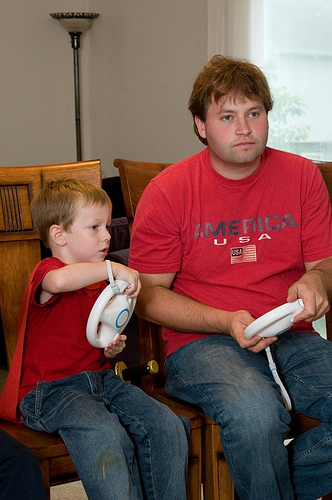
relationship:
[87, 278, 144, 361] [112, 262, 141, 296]
steering wheel in hands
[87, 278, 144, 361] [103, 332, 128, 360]
steering wheel in hands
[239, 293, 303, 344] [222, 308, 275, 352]
steering wheel in hands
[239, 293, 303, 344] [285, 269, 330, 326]
steering wheel in hands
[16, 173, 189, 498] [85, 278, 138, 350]
kid holding steering wheel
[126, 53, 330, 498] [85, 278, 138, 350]
man playing steering wheel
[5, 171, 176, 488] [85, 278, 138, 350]
kid playing steering wheel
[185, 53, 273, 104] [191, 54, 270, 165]
hair on head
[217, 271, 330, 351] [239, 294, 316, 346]
hands holding steering wheel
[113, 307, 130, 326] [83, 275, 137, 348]
circle on middle of wheel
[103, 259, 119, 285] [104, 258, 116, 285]
strap around strap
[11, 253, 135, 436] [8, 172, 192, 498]
shirt on kid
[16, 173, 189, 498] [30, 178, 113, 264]
kid has boyhead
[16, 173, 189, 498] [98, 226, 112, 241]
kid has nose